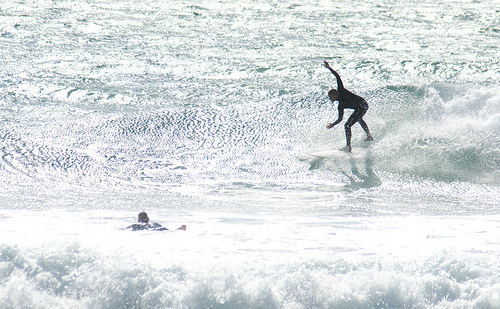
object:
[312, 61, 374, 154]
man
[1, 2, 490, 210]
water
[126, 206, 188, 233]
person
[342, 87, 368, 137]
wetsuit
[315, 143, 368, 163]
surfboard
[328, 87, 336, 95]
hair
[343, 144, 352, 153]
foot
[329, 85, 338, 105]
head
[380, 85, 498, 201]
wave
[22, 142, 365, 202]
ripples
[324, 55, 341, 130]
arms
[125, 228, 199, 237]
surfboard